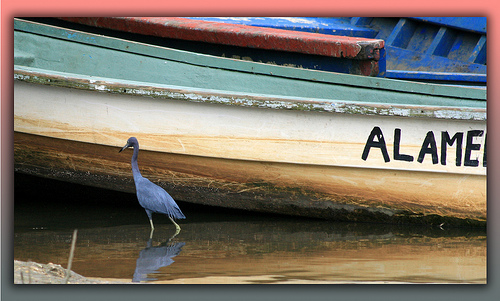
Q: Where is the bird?
A: In water.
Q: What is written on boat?
A: Name.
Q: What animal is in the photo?
A: Bird.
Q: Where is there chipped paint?
A: Side of boat.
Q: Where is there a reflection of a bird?
A: In water.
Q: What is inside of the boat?
A: Blue frame.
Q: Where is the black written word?
A: On the side of the boat.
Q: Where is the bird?
A: Next to the boat.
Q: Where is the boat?
A: Next to the bird.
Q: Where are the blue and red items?
A: Behind the white boat.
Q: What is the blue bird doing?
A: Walking in the water.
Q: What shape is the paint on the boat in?
A: It is peeling.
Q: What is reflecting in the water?
A: The boat and the bird.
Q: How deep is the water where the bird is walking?
A: Only a couple of inches.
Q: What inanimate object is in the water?
A: A boat.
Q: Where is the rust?
A: On the red metal object.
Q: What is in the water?
A: Bird.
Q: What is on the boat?
A: ALAME.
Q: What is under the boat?
A: Water.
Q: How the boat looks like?
A: Old.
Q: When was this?
A: Daytime.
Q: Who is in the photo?
A: Nobody.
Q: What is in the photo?
A: A bird.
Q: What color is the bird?
A: Blue.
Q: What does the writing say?
A: ALAME.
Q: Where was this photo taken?
A: On the river.